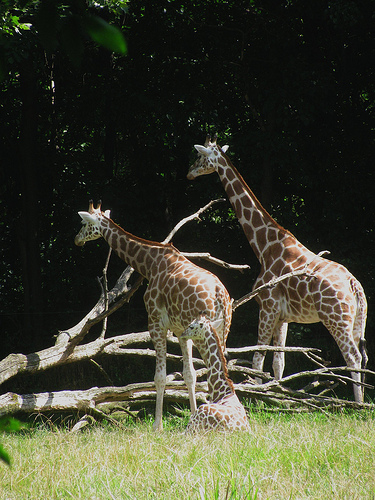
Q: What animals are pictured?
A: Giraffes.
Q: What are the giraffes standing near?
A: Fallen tree.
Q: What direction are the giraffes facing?
A: Left.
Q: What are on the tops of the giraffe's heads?
A: Horns.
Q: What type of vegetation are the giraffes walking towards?
A: Trees.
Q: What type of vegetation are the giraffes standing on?
A: Grass.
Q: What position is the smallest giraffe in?
A: Lying down.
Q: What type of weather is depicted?
A: Sunny and clear.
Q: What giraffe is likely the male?
A: The one on the right.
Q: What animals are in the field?
A: Giraffes.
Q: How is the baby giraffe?
A: Sitting down.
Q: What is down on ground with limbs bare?
A: Tree.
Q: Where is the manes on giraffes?
A: Neck.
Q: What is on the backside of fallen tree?
A: Trees.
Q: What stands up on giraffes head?
A: Horns.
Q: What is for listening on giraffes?
A: Ears.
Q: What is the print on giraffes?
A: Spotted.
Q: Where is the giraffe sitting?
A: Grass.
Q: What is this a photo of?
A: 3 giraffes.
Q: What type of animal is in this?
A: Giraffes.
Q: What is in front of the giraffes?
A: A dead fallen tree.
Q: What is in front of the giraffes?
A: Thick forest of trees.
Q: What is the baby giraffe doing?
A: Sitting in the grass.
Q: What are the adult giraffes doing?
A: Staring into the forest.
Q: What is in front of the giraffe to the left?
A: Trunks of a tree on the ground.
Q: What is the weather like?
A: Warm and sunny.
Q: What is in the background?
A: Tall trees.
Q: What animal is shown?
A: Giraffe.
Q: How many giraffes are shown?
A: Three.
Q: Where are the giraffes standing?
A: The grass.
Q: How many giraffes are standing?
A: Two.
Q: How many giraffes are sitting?
A: One.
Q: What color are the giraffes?
A: Brown and white.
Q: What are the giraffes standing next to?
A: A branch.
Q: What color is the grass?
A: Green.